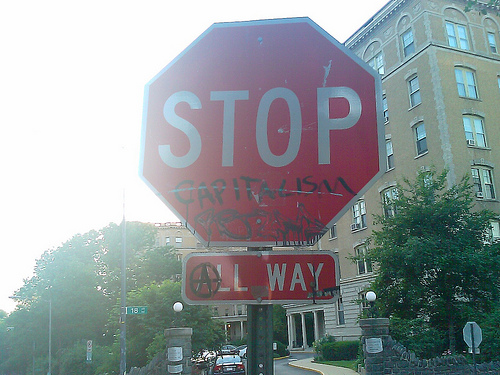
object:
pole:
[246, 247, 273, 374]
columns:
[284, 306, 326, 353]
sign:
[138, 16, 386, 247]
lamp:
[365, 291, 376, 302]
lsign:
[365, 338, 383, 354]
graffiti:
[190, 203, 325, 245]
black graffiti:
[160, 170, 354, 210]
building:
[281, 0, 498, 352]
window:
[455, 69, 477, 99]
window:
[367, 52, 385, 76]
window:
[471, 168, 495, 199]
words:
[174, 179, 194, 203]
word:
[318, 176, 357, 197]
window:
[386, 140, 394, 171]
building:
[133, 222, 245, 347]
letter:
[317, 86, 363, 164]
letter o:
[256, 87, 303, 168]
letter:
[158, 91, 202, 169]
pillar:
[358, 317, 390, 373]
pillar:
[164, 328, 193, 374]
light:
[173, 301, 184, 312]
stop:
[158, 86, 362, 168]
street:
[208, 347, 310, 371]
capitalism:
[174, 176, 356, 204]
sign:
[182, 250, 340, 305]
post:
[118, 202, 126, 374]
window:
[410, 76, 421, 107]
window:
[463, 116, 487, 147]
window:
[446, 21, 469, 50]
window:
[383, 96, 390, 123]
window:
[416, 123, 428, 154]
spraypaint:
[173, 170, 361, 237]